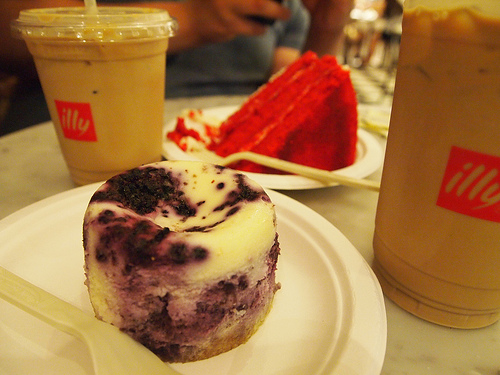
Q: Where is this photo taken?
A: In a restaurant.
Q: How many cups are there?
A: Two.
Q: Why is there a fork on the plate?
A: It is there for the cake to be eaten.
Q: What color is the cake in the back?
A: Red.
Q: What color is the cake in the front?
A: Blue and white.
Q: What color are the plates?
A: White.